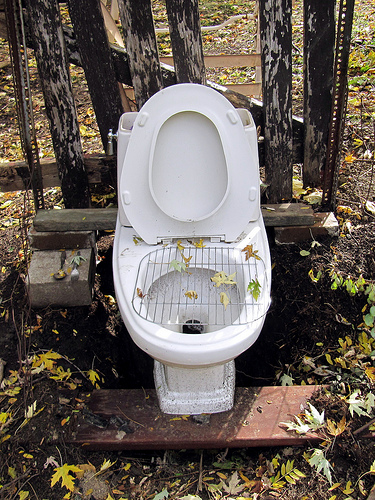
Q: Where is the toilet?
A: On top of a hole.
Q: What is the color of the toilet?
A: White.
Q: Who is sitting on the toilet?
A: No one.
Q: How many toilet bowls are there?
A: One.